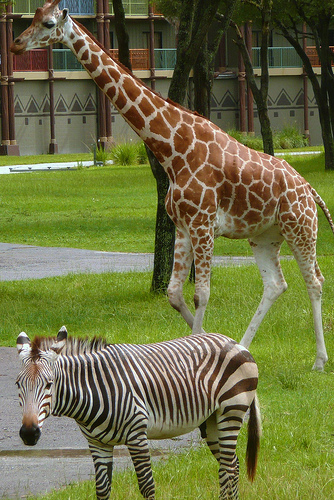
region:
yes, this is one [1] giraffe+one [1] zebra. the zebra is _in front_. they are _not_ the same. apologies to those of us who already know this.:
[0, 0, 333, 499]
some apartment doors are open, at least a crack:
[50, 26, 283, 70]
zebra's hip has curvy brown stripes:
[187, 329, 234, 415]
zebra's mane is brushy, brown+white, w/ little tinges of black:
[27, 332, 115, 363]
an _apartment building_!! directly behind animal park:
[1, 0, 331, 158]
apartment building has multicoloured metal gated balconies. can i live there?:
[1, 13, 330, 156]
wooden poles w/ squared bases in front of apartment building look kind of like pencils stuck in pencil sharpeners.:
[0, 1, 314, 159]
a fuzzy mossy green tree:
[160, 0, 241, 130]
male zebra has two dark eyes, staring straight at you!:
[10, 369, 56, 393]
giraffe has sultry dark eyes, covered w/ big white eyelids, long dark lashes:
[38, 18, 58, 30]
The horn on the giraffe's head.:
[46, 0, 58, 2]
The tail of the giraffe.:
[240, 391, 256, 465]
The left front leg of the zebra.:
[78, 432, 109, 488]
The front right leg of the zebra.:
[119, 431, 148, 487]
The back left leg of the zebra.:
[199, 411, 229, 489]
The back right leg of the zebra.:
[208, 403, 240, 490]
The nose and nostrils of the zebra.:
[11, 416, 35, 434]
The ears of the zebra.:
[4, 318, 62, 351]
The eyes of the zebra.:
[8, 377, 55, 392]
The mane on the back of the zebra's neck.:
[34, 325, 107, 350]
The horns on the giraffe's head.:
[40, 0, 61, 9]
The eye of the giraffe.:
[40, 16, 54, 29]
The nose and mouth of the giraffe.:
[10, 35, 28, 55]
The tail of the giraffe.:
[311, 185, 333, 233]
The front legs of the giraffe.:
[153, 205, 226, 335]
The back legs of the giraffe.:
[239, 235, 326, 385]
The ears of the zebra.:
[10, 329, 72, 355]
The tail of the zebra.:
[249, 395, 263, 481]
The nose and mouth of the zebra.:
[15, 418, 45, 444]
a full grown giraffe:
[8, 2, 298, 337]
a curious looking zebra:
[6, 308, 277, 498]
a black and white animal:
[9, 307, 276, 485]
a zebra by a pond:
[0, 329, 272, 487]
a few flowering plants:
[84, 124, 143, 166]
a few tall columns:
[0, 82, 27, 160]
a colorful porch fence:
[22, 35, 309, 78]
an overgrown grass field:
[90, 270, 329, 483]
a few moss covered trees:
[136, 1, 328, 173]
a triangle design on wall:
[14, 79, 92, 132]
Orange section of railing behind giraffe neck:
[109, 44, 150, 73]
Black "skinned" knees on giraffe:
[161, 295, 217, 313]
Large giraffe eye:
[40, 16, 57, 30]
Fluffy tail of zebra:
[240, 404, 274, 487]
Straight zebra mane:
[28, 331, 111, 353]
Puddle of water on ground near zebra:
[1, 440, 172, 467]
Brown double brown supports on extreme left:
[0, 1, 21, 155]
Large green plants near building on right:
[225, 123, 309, 151]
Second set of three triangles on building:
[55, 91, 98, 118]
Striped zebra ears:
[9, 321, 75, 358]